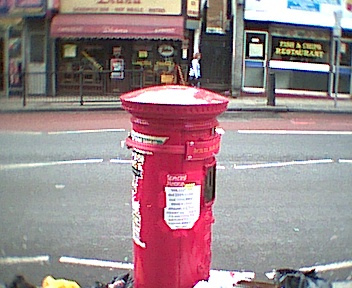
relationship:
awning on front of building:
[44, 14, 187, 46] [54, 0, 187, 99]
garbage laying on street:
[189, 267, 335, 286] [0, 113, 350, 287]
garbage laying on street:
[40, 275, 80, 288] [0, 113, 350, 287]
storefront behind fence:
[49, 8, 194, 98] [2, 64, 148, 110]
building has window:
[49, 0, 187, 99] [60, 41, 102, 81]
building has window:
[231, 0, 350, 100] [270, 36, 330, 65]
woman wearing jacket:
[187, 51, 203, 87] [188, 59, 199, 75]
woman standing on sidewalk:
[189, 50, 203, 83] [1, 95, 351, 114]